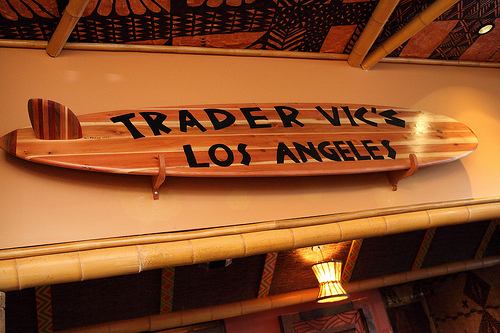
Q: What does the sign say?
A: Trader Vic's Los Angeles.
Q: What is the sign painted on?
A: A surfboard.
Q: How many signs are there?
A: One.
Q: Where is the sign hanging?
A: On the wall.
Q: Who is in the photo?
A: Nobody.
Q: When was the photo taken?
A: Nighttime.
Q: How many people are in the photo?
A: None.